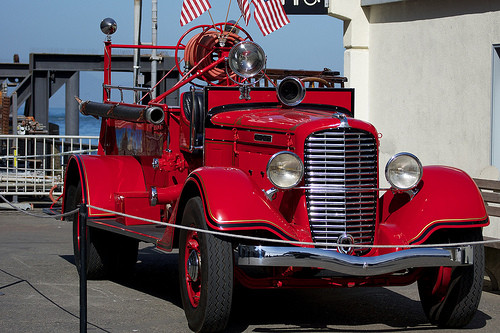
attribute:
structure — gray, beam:
[2, 40, 223, 183]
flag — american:
[248, 0, 299, 38]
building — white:
[321, 0, 498, 287]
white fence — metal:
[1, 132, 98, 198]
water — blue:
[40, 97, 110, 151]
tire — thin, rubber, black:
[178, 195, 234, 332]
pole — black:
[77, 94, 161, 124]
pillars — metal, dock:
[26, 56, 86, 138]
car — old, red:
[101, 32, 483, 293]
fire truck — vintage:
[46, 4, 498, 330]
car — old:
[60, 17, 490, 330]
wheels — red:
[171, 190, 245, 331]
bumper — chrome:
[223, 226, 490, 289]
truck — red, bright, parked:
[55, 17, 495, 331]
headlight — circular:
[263, 152, 307, 192]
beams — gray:
[2, 49, 342, 166]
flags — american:
[166, 10, 285, 52]